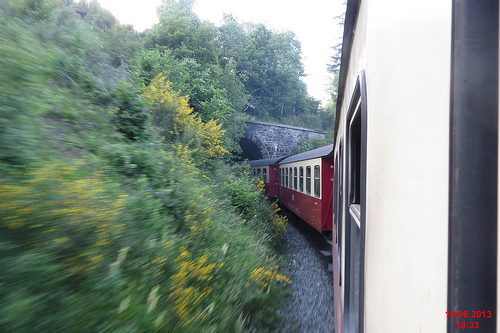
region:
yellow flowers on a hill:
[144, 69, 232, 161]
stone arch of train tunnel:
[231, 114, 324, 174]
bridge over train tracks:
[235, 106, 330, 142]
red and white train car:
[273, 140, 333, 235]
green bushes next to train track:
[3, 0, 278, 327]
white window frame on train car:
[274, 156, 325, 201]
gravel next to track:
[262, 196, 338, 332]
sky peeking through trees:
[97, 0, 347, 119]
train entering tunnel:
[241, 1, 495, 332]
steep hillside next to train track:
[3, 0, 287, 332]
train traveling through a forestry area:
[13, 7, 482, 319]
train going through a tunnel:
[150, 52, 487, 331]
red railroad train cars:
[192, 90, 332, 320]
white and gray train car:
[328, 39, 463, 331]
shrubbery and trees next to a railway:
[0, 2, 389, 329]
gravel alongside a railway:
[242, 172, 362, 323]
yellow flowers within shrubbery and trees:
[90, 32, 321, 324]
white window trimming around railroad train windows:
[264, 148, 332, 244]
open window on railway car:
[325, 71, 425, 267]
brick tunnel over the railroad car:
[195, 100, 340, 220]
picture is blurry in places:
[7, 85, 172, 326]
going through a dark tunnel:
[230, 127, 292, 187]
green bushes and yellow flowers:
[114, 71, 243, 330]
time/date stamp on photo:
[437, 288, 498, 330]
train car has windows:
[279, 160, 326, 197]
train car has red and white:
[267, 153, 331, 234]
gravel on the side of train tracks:
[282, 213, 340, 331]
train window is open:
[322, 81, 370, 238]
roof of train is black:
[281, 140, 333, 165]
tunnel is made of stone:
[254, 125, 301, 155]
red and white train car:
[243, 155, 281, 209]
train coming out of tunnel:
[228, 126, 268, 166]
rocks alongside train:
[262, 210, 330, 330]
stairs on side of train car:
[316, 230, 333, 270]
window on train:
[311, 163, 323, 201]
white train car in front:
[327, 0, 492, 332]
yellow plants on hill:
[138, 69, 226, 161]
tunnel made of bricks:
[231, 117, 321, 167]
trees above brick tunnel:
[211, 12, 313, 119]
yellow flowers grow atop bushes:
[176, 249, 216, 302]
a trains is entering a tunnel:
[259, 0, 494, 331]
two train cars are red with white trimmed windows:
[257, 148, 331, 198]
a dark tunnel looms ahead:
[237, 115, 282, 163]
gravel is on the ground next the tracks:
[293, 229, 320, 324]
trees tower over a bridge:
[172, 14, 313, 119]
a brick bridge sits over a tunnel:
[250, 117, 328, 136]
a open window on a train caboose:
[343, 84, 366, 331]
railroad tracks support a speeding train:
[296, 221, 312, 233]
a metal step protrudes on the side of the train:
[323, 249, 331, 258]